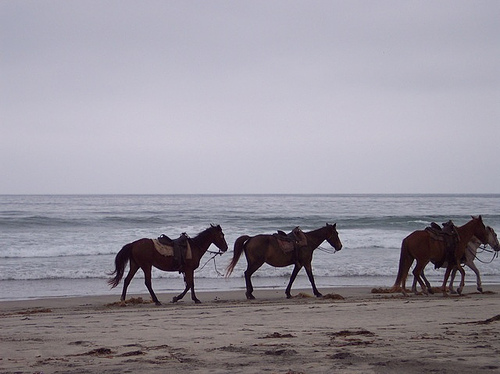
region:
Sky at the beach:
[2, 1, 499, 190]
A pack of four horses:
[108, 210, 498, 307]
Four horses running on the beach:
[101, 210, 498, 309]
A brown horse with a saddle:
[105, 217, 227, 305]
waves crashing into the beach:
[0, 236, 110, 287]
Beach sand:
[1, 299, 498, 372]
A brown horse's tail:
[226, 233, 256, 276]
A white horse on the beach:
[458, 218, 498, 295]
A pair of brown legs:
[173, 268, 205, 303]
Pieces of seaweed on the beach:
[323, 282, 398, 309]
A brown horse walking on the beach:
[112, 221, 226, 319]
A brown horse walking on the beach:
[234, 223, 344, 297]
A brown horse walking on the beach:
[391, 213, 489, 284]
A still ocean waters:
[35, 196, 291, 224]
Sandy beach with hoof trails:
[88, 315, 388, 370]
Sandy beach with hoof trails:
[114, 282, 464, 306]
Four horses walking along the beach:
[91, 218, 498, 291]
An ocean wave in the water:
[358, 214, 428, 226]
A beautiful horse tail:
[109, 247, 130, 293]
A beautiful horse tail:
[232, 226, 247, 269]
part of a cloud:
[275, 0, 317, 75]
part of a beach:
[321, 315, 348, 346]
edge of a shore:
[54, 278, 109, 335]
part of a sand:
[263, 300, 293, 350]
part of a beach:
[259, 316, 291, 353]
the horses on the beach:
[105, 215, 498, 310]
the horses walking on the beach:
[100, 215, 495, 305]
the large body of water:
[0, 185, 490, 271]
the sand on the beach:
[15, 287, 495, 368]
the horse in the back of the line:
[105, 215, 225, 305]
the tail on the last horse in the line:
[105, 240, 130, 286]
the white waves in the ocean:
[330, 221, 410, 251]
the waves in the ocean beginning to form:
[2, 200, 172, 227]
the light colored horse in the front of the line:
[450, 215, 495, 292]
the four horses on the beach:
[105, 215, 496, 303]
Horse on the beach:
[121, 236, 224, 298]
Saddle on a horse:
[150, 236, 193, 260]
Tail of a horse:
[111, 253, 128, 283]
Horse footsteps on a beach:
[109, 296, 219, 306]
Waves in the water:
[48, 206, 129, 228]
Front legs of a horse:
[283, 269, 323, 296]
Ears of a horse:
[323, 220, 338, 226]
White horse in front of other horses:
[469, 229, 496, 284]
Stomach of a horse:
[267, 253, 297, 269]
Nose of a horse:
[336, 239, 345, 250]